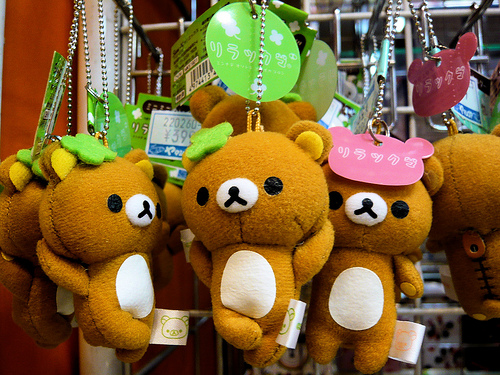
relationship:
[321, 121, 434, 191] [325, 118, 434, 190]
tag on head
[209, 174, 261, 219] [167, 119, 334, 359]
snout of bear